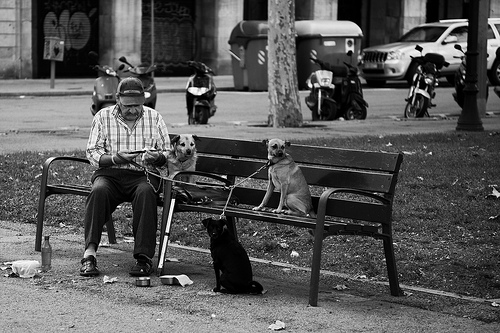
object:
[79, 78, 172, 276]
man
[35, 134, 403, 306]
bench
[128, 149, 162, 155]
object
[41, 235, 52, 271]
bottle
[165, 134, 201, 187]
dog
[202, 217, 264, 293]
dog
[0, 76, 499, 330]
ground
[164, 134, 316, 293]
together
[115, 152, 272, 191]
leash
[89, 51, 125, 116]
motorcycles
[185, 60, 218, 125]
motorcycle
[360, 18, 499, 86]
suv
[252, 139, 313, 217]
dog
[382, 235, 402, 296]
leg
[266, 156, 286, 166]
collar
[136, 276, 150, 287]
bowl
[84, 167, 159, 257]
pants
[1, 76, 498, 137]
road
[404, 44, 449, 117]
motorcycle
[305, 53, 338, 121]
motorcycle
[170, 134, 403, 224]
back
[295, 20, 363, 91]
trash bin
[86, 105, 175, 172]
shirt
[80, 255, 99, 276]
shoes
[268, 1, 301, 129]
tree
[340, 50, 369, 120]
motorcycle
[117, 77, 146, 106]
hat